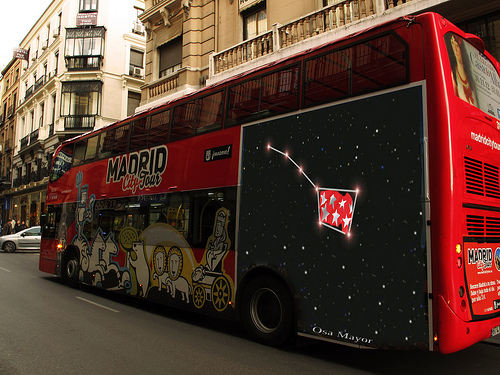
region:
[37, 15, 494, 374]
a red bus on the street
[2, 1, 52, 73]
a sky with clouds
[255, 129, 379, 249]
a big dipper on the side of the bus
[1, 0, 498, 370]
a scene of downtown area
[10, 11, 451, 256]
a tan row of buildings in the background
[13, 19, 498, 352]
a scene during the day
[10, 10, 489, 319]
a scene outside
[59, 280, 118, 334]
a white line painted on the road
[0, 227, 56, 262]
a car in the background on the street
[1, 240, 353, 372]
a stretch of road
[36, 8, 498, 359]
The bus is red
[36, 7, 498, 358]
The bus is double decker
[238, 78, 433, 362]
The side of the bus has Osa Mayor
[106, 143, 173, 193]
The middle of the bus says Madrid City Tour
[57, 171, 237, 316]
The side of the bus has a mural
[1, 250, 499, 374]
The street is grey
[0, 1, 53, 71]
The sky is overcast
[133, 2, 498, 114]
There is balconies above the bus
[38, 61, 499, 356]
The bus is two floors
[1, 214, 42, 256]
The car is silver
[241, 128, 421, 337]
the big dipper on the side of the bus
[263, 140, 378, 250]
the big dipper is red and silver stars in the middle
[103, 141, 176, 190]
madrid tours is on the side of the bus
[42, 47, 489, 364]
the bus is a tour bus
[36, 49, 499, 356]
the bus is red and black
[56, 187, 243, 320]
the bus has a muriel on the side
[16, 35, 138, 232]
a building with apartments above the stores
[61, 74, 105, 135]
balcony on the corner of the building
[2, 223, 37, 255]
car driving through intersection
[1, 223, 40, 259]
the car is silver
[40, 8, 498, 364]
The bus is double decker.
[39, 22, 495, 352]
the bus is red.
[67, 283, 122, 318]
Line on street is white.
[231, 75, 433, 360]
The advertisement is black.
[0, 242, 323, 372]
The street is concrete.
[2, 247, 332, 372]
The street is grey.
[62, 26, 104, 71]
The curtains are white.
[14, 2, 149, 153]
the building is tan.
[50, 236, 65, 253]
the light is on.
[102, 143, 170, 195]
the text is black and red.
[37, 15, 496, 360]
a big red tour bus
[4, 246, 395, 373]
city street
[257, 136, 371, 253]
constellation on the side of the bus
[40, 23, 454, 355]
the side of the bus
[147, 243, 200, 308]
two lions on the side of the bus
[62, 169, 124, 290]
a blue gladiator with two horses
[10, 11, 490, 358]
city street of Madrid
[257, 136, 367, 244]
the Big Dipper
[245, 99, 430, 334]
night sky